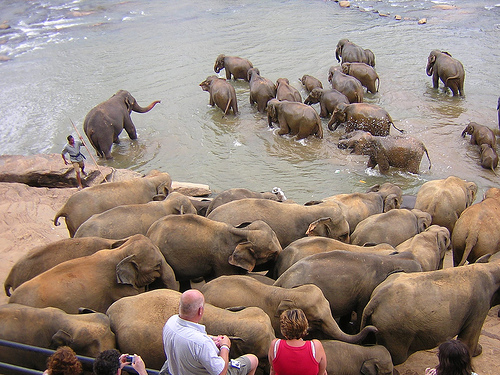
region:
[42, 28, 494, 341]
large group of grey elephants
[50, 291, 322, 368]
people watching the elephants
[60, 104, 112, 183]
man carrying a large brown stick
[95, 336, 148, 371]
person taking a photograph of elephants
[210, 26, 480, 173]
elephants in the water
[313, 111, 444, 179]
elephant spraying water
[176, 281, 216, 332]
man with very little white hair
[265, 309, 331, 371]
woman wearing a red tank top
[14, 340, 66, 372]
black metal guard rail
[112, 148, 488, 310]
elephants heading into the water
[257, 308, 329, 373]
woman in red shirt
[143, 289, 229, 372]
bald man in white shirt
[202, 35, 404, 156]
group of small elephants in water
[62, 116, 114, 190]
man holding a large wooden pole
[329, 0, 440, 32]
small rocks in the water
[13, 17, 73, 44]
small ripples on water surface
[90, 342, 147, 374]
person with black hair taking photo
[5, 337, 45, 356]
grey metal guard railing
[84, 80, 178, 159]
large elephant standing in water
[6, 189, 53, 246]
large brown boulders on side of water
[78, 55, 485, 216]
Elephants in the water.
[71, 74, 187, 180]
Elephant in the water.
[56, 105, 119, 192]
Man by the elephant.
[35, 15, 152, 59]
Waves in the water.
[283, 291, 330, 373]
Woman in a red shirt.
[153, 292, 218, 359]
Man in a white shirt.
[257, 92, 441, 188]
Elephants playing in the water.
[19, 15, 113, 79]
White waves on the water.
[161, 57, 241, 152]
Reflection on the water.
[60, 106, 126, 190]
Man with a pole.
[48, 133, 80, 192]
man next to water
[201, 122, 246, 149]
ripples on water surface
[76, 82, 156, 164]
elephant in the water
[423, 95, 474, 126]
shadow of the elephant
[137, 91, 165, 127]
trunk of an elephant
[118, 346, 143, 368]
camera in person's hand's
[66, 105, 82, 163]
pole in man's hand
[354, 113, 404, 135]
water in the air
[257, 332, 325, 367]
tank top on woman's shoulders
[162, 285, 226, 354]
man watching the elephant's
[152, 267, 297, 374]
People watching the elephants.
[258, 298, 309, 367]
Woman with red shirt.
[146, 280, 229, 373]
Man with white shirt.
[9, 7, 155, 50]
White waves on the water.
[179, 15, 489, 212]
A herd of elephants in the water.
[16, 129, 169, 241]
Man by the elephant.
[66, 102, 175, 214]
Man with a pole.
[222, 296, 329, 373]
Woman with white straps showing.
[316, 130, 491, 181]
Elephant spraying the water.